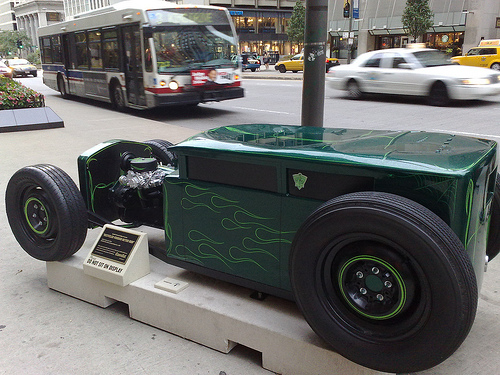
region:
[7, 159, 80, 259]
this is a wheel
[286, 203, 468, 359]
this is a wheel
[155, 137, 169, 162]
this is a wheel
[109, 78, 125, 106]
this is a wheel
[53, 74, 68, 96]
this is a wheel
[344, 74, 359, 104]
this is a wheel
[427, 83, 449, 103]
this is a wheel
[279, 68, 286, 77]
this is a wheel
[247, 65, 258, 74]
this is a wheel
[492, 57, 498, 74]
this is a wheel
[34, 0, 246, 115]
City bus on the street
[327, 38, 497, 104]
White taxi on the street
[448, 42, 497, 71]
Yellow taxi on the street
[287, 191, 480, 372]
Big wheel on display vehicle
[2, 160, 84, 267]
Small front wheel on display vehicle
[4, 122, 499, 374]
Green vehicle on display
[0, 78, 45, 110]
Flower bed on the sidewalk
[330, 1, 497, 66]
Department store across the street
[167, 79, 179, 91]
Bus has headlight on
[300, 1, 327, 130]
Power pole near street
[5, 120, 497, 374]
the car put on display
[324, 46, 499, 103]
the white car in motion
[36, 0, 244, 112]
the bus on the street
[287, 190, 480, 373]
the large wheel on the car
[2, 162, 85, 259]
the small wheel on the car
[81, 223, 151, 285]
the sign near the car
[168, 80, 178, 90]
the white light on the bus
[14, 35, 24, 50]
the green traffic light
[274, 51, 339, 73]
the yellow car on the street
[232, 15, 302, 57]
the windows and doors on the building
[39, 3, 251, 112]
moving large city transportation bus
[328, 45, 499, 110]
white taxi cab driving in traffic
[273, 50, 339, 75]
yellow taxi cab with brake lights on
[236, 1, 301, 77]
large store front with lights on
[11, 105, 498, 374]
large green motorbox with tires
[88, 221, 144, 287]
black and gold plaque with information listed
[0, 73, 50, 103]
raised ornamental flower beds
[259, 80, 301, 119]
very busy filled city street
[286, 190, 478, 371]
large black rubber tire with lime green rim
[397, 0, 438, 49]
skinny tree planted on city sidewalk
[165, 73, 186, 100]
light on a bus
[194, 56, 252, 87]
a sign on the bus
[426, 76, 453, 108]
a tire on the car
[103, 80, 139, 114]
a tire on the bus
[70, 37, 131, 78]
windows on a bus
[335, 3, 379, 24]
a sign on the building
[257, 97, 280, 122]
white lines on the street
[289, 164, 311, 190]
a sticker on the car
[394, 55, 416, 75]
a mirror on a car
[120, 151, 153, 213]
engine in a car